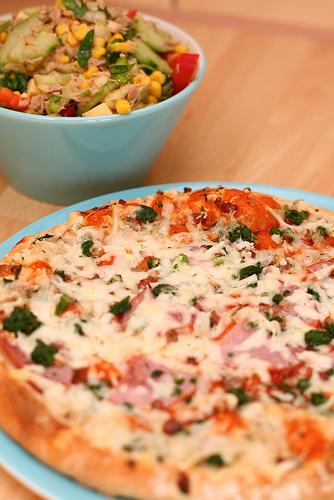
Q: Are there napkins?
A: No, there are no napkins.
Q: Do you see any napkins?
A: No, there are no napkins.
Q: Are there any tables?
A: Yes, there is a table.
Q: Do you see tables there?
A: Yes, there is a table.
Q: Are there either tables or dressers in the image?
A: Yes, there is a table.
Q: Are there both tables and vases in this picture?
A: No, there is a table but no vases.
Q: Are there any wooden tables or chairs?
A: Yes, there is a wood table.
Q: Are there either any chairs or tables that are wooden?
A: Yes, the table is wooden.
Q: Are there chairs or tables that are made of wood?
A: Yes, the table is made of wood.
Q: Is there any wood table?
A: Yes, there is a table that is made of wood.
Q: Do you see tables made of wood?
A: Yes, there is a table that is made of wood.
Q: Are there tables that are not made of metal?
A: Yes, there is a table that is made of wood.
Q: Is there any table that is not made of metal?
A: Yes, there is a table that is made of wood.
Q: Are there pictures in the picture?
A: No, there are no pictures.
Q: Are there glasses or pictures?
A: No, there are no pictures or glasses.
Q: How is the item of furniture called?
A: The piece of furniture is a table.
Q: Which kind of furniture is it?
A: The piece of furniture is a table.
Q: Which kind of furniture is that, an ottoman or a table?
A: This is a table.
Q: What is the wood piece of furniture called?
A: The piece of furniture is a table.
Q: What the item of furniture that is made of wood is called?
A: The piece of furniture is a table.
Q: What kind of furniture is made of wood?
A: The furniture is a table.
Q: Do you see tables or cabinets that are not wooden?
A: No, there is a table but it is wooden.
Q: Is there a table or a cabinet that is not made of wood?
A: No, there is a table but it is made of wood.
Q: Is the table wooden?
A: Yes, the table is wooden.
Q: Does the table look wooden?
A: Yes, the table is wooden.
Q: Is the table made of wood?
A: Yes, the table is made of wood.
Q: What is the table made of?
A: The table is made of wood.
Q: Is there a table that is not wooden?
A: No, there is a table but it is wooden.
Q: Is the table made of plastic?
A: No, the table is made of wood.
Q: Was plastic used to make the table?
A: No, the table is made of wood.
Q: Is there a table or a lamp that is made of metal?
A: No, there is a table but it is made of wood.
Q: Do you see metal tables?
A: No, there is a table but it is made of wood.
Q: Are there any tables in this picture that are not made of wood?
A: No, there is a table but it is made of wood.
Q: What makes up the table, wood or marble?
A: The table is made of wood.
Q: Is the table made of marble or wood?
A: The table is made of wood.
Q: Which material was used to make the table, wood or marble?
A: The table is made of wood.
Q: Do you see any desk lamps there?
A: No, there are no desk lamps.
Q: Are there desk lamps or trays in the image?
A: No, there are no desk lamps or trays.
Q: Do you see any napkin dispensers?
A: No, there are no napkin dispensers.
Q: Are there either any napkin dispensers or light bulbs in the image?
A: No, there are no napkin dispensers or light bulbs.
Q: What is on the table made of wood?
A: The bowl is on the table.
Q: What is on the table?
A: The bowl is on the table.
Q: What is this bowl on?
A: The bowl is on the table.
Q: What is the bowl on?
A: The bowl is on the table.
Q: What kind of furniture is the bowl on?
A: The bowl is on the table.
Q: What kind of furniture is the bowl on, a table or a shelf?
A: The bowl is on a table.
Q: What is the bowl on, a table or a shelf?
A: The bowl is on a table.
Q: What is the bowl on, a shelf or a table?
A: The bowl is on a table.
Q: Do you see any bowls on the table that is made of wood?
A: Yes, there is a bowl on the table.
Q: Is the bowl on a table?
A: Yes, the bowl is on a table.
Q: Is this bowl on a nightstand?
A: No, the bowl is on a table.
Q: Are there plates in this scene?
A: Yes, there is a plate.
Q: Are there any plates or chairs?
A: Yes, there is a plate.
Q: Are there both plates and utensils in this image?
A: No, there is a plate but no utensils.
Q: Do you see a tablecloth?
A: No, there are no tablecloths.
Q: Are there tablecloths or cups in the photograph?
A: No, there are no tablecloths or cups.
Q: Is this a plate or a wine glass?
A: This is a plate.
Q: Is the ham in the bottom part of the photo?
A: Yes, the ham is in the bottom of the image.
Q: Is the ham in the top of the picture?
A: No, the ham is in the bottom of the image.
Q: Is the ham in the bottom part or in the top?
A: The ham is in the bottom of the image.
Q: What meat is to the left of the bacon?
A: The meat is ham.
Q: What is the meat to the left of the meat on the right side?
A: The meat is ham.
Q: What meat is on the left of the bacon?
A: The meat is ham.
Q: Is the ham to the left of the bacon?
A: Yes, the ham is to the left of the bacon.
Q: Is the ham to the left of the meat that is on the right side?
A: Yes, the ham is to the left of the bacon.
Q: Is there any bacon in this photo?
A: Yes, there is bacon.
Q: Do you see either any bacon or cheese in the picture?
A: Yes, there is bacon.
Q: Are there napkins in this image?
A: No, there are no napkins.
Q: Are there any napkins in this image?
A: No, there are no napkins.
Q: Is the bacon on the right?
A: Yes, the bacon is on the right of the image.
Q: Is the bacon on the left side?
A: No, the bacon is on the right of the image.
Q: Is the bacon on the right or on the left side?
A: The bacon is on the right of the image.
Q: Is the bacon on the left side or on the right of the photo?
A: The bacon is on the right of the image.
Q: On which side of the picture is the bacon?
A: The bacon is on the right of the image.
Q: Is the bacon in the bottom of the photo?
A: Yes, the bacon is in the bottom of the image.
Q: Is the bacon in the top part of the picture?
A: No, the bacon is in the bottom of the image.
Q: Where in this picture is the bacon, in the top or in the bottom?
A: The bacon is in the bottom of the image.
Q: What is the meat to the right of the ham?
A: The meat is bacon.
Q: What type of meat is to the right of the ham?
A: The meat is bacon.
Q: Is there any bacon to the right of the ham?
A: Yes, there is bacon to the right of the ham.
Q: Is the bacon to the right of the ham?
A: Yes, the bacon is to the right of the ham.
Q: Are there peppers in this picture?
A: Yes, there is a pepper.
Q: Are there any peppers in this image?
A: Yes, there is a pepper.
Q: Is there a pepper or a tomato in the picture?
A: Yes, there is a pepper.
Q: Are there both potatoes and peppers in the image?
A: No, there is a pepper but no potatoes.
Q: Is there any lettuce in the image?
A: No, there is no lettuce.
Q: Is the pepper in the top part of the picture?
A: Yes, the pepper is in the top of the image.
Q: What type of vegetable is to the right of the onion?
A: The vegetable is a pepper.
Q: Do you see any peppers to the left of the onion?
A: No, the pepper is to the right of the onion.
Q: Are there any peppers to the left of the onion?
A: No, the pepper is to the right of the onion.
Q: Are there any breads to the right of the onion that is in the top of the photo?
A: No, there is a pepper to the right of the onion.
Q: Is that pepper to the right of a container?
A: No, the pepper is to the right of the onion.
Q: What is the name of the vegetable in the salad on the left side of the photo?
A: The vegetable is a pepper.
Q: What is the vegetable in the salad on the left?
A: The vegetable is a pepper.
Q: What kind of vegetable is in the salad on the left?
A: The vegetable is a pepper.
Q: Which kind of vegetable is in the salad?
A: The vegetable is a pepper.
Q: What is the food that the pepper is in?
A: The food is salad.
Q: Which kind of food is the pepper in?
A: The pepper is in the salad.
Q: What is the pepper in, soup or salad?
A: The pepper is in salad.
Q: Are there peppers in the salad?
A: Yes, there is a pepper in the salad.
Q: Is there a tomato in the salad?
A: No, there is a pepper in the salad.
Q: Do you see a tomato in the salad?
A: No, there is a pepper in the salad.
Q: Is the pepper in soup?
A: No, the pepper is in the salad.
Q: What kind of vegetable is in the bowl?
A: The vegetable is a pepper.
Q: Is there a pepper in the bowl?
A: Yes, there is a pepper in the bowl.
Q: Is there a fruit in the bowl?
A: No, there is a pepper in the bowl.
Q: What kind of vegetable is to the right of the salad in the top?
A: The vegetable is a pepper.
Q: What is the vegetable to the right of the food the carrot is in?
A: The vegetable is a pepper.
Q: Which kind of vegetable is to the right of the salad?
A: The vegetable is a pepper.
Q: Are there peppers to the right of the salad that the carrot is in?
A: Yes, there is a pepper to the right of the salad.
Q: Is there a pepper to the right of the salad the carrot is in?
A: Yes, there is a pepper to the right of the salad.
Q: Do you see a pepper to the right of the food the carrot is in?
A: Yes, there is a pepper to the right of the salad.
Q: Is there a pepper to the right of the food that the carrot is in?
A: Yes, there is a pepper to the right of the salad.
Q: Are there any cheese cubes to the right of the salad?
A: No, there is a pepper to the right of the salad.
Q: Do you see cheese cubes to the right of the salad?
A: No, there is a pepper to the right of the salad.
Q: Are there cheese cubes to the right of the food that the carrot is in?
A: No, there is a pepper to the right of the salad.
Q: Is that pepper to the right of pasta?
A: No, the pepper is to the right of the salad.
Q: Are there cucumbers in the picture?
A: Yes, there is a cucumber.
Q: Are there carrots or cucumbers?
A: Yes, there is a cucumber.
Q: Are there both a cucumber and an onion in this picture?
A: Yes, there are both a cucumber and an onion.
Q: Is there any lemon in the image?
A: No, there are no lemons.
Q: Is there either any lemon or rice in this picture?
A: No, there are no lemons or rice.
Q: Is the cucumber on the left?
A: Yes, the cucumber is on the left of the image.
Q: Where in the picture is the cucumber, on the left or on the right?
A: The cucumber is on the left of the image.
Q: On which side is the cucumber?
A: The cucumber is on the left of the image.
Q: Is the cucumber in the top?
A: Yes, the cucumber is in the top of the image.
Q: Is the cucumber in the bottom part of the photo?
A: No, the cucumber is in the top of the image.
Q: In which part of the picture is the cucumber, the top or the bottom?
A: The cucumber is in the top of the image.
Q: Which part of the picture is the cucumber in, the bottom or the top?
A: The cucumber is in the top of the image.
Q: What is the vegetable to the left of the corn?
A: The vegetable is a cucumber.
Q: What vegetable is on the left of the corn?
A: The vegetable is a cucumber.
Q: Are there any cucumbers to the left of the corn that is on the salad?
A: Yes, there is a cucumber to the left of the corn.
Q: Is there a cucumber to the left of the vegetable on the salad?
A: Yes, there is a cucumber to the left of the corn.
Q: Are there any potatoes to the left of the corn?
A: No, there is a cucumber to the left of the corn.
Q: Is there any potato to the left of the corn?
A: No, there is a cucumber to the left of the corn.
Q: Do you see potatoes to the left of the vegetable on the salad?
A: No, there is a cucumber to the left of the corn.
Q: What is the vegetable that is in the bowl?
A: The vegetable is a cucumber.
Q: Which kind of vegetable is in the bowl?
A: The vegetable is a cucumber.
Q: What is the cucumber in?
A: The cucumber is in the bowl.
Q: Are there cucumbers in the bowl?
A: Yes, there is a cucumber in the bowl.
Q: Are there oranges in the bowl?
A: No, there is a cucumber in the bowl.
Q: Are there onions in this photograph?
A: Yes, there is an onion.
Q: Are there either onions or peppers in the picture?
A: Yes, there is an onion.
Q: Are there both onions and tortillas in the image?
A: No, there is an onion but no tortillas.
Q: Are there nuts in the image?
A: No, there are no nuts.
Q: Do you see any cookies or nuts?
A: No, there are no nuts or cookies.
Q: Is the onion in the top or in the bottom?
A: The onion is in the top of the image.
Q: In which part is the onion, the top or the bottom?
A: The onion is in the top of the image.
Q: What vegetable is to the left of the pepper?
A: The vegetable is an onion.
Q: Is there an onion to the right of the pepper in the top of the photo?
A: No, the onion is to the left of the pepper.